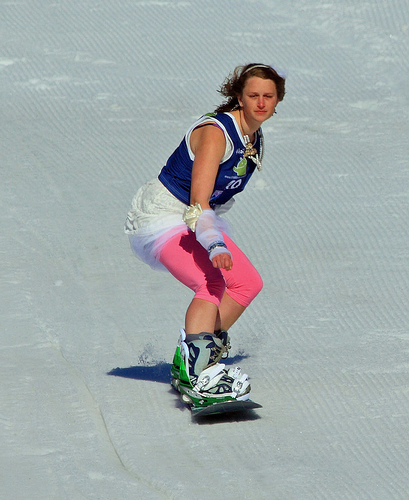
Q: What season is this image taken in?
A: Winter.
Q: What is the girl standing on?
A: Snowboard.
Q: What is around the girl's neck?
A: Necklace.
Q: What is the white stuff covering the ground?
A: Snow.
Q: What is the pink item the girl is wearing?
A: Pants.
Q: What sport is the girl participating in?
A: Snowboarding.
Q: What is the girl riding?
A: Snowboard.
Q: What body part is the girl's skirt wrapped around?
A: Arm.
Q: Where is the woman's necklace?
A: Around neck.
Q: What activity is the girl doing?
A: Snowboarding.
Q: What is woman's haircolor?
A: Brown.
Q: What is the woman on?
A: A snowboard.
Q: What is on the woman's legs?
A: Pink leggings.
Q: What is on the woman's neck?
A: A necklace.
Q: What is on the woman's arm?
A: Lace and a wristband.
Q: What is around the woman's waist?
A: White lace.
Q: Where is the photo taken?
A: A mountain.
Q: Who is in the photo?
A: A woman.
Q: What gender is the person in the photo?
A: Female.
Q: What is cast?
A: Shadow.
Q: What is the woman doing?
A: Snowboarding.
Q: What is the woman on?
A: Snowboard.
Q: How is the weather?
A: Sunny.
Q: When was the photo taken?
A: Daytime.